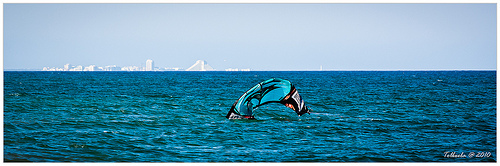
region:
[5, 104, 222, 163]
calm waves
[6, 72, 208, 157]
deep blue ocean water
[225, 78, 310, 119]
sail for water sport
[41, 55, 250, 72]
cluster of white buildings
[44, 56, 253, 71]
city off in the distance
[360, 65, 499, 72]
horizon, where water meets sky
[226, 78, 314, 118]
parachute for safe landing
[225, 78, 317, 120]
orange, black, white and blue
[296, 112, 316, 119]
edge for strings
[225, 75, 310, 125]
Wind sail hanging down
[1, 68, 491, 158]
Large body of blue water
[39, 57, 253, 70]
City in the distance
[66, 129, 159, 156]
A wave in the ocean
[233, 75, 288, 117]
Turquoise blue geometric pattern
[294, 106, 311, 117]
Top of a wind sail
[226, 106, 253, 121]
Base of a wind sail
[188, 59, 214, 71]
A triangular shaped building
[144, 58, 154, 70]
A tall city building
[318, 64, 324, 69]
A building by itself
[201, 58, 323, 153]
a parasail in the water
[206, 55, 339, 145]
the parachute is blue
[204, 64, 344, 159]
there is a black pattern on the sail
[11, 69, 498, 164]
the water is very contrasty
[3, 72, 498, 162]
the water is dark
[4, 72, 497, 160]
the water is blue and green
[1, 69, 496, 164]
the water is a bluish green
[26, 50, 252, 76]
a city in the distance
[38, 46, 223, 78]
the buildings are white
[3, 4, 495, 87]
the sky is hazy and light blue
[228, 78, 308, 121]
a blue kite landing in the water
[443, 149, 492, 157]
photo credit in the corner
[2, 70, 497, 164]
wavy blue ocean water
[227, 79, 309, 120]
black markings on a kite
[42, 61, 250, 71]
white cast light on a city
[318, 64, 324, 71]
a white tower in the distance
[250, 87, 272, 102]
a black design on a kite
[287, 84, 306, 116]
the right curved side of a kite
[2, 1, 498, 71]
bright blue sky over the ocean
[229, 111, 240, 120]
white on the left corner of the kite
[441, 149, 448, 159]
white print style letter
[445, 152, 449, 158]
white print style letter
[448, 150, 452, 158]
white print style letter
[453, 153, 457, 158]
white print style letter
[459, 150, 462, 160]
white print style letter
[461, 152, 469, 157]
white print style letter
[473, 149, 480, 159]
white print style number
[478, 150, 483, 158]
white print style number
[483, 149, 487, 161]
white print style number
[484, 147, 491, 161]
white print style number